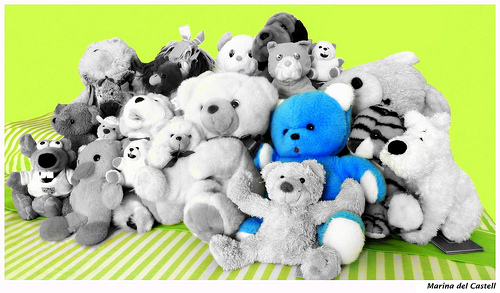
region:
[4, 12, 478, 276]
A variety of stuffed animals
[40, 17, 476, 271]
s pile of stuffed animals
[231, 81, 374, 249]
this is a teddy bear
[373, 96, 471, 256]
this is a stuffed dog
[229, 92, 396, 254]
the teddy bear is blue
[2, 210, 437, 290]
green stripes on floor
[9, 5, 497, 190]
green background behind bears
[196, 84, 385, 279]
small bear in front of larger bear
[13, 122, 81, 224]
big teeth on stuffed animal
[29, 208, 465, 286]
white stripes on floor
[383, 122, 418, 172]
a black dog nose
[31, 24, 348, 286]
this is partially black and white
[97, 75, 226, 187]
part of this is monochromatic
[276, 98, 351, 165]
this bear is in color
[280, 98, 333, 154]
this is a teddy bear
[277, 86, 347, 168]
the bear is blue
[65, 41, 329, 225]
these are stuffed animals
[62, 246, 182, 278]
the ground is green and white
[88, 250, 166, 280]
the ground here is striped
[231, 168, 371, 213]
this bear has it's hands out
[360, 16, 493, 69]
the background is lime green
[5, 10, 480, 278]
stuffed animals on a bed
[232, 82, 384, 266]
blue teddy bear in pile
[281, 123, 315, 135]
teddy bear has two eyes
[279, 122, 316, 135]
teddy bears eyes are black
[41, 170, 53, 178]
stuffed animal has large teeth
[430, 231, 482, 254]
small book under stuffed animal pile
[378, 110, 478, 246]
stuffed animal has longer fur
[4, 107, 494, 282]
bed sheet has green stripes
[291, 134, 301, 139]
stuffed animal has black nose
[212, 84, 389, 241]
one bear is blue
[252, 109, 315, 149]
bear has black eyes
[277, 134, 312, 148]
bear has black nose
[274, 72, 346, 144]
bear has white ears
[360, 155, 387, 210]
blue and white paws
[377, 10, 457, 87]
green wall behind toys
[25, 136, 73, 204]
mouse has big teeth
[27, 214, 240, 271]
green and white sheet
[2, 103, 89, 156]
green and white pillow